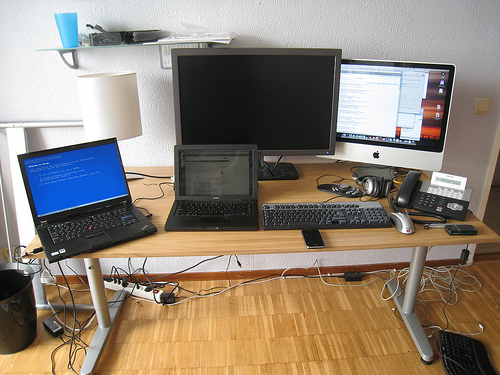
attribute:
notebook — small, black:
[162, 144, 259, 233]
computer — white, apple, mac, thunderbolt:
[326, 54, 456, 172]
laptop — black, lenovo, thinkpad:
[11, 138, 159, 265]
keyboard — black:
[434, 327, 497, 374]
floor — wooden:
[3, 257, 498, 375]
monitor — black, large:
[168, 47, 342, 182]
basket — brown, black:
[1, 261, 37, 357]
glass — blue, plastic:
[52, 11, 81, 47]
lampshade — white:
[76, 72, 144, 143]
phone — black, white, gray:
[394, 169, 471, 223]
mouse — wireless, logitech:
[388, 209, 416, 235]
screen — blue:
[15, 141, 131, 218]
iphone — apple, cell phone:
[299, 229, 325, 250]